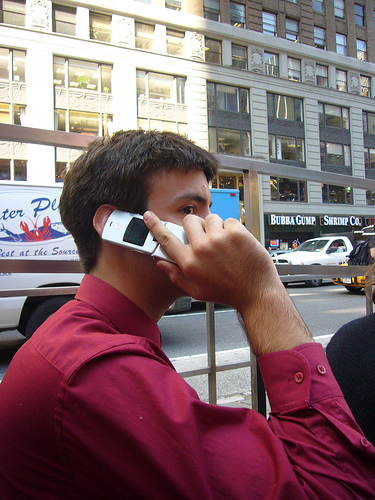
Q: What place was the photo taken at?
A: It was taken at the road.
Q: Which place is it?
A: It is a road.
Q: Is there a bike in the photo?
A: No, there are no bikes.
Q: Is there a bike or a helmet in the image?
A: No, there are no bikes or helmets.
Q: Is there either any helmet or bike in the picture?
A: No, there are no bikes or helmets.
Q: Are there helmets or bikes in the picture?
A: No, there are no bikes or helmets.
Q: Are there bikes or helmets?
A: No, there are no bikes or helmets.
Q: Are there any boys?
A: No, there are no boys.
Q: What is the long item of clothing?
A: The clothing item is a shirt.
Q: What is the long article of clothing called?
A: The clothing item is a shirt.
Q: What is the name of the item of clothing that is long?
A: The clothing item is a shirt.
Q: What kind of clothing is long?
A: The clothing is a shirt.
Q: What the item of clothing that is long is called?
A: The clothing item is a shirt.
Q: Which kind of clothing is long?
A: The clothing is a shirt.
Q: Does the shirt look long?
A: Yes, the shirt is long.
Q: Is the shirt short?
A: No, the shirt is long.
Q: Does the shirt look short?
A: No, the shirt is long.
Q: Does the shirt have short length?
A: No, the shirt is long.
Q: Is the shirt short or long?
A: The shirt is long.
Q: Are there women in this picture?
A: No, there are no women.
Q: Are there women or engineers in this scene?
A: No, there are no women or engineers.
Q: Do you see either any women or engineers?
A: No, there are no women or engineers.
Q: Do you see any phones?
A: Yes, there is a phone.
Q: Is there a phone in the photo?
A: Yes, there is a phone.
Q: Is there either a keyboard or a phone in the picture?
A: Yes, there is a phone.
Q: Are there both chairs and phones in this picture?
A: No, there is a phone but no chairs.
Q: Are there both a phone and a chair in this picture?
A: No, there is a phone but no chairs.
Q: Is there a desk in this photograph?
A: No, there are no desks.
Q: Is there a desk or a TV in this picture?
A: No, there are no desks or televisions.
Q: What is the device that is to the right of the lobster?
A: The device is a phone.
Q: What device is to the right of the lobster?
A: The device is a phone.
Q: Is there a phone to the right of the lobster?
A: Yes, there is a phone to the right of the lobster.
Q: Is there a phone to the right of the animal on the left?
A: Yes, there is a phone to the right of the lobster.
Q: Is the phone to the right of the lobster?
A: Yes, the phone is to the right of the lobster.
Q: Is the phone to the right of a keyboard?
A: No, the phone is to the right of the lobster.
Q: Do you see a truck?
A: Yes, there is a truck.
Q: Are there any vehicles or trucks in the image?
A: Yes, there is a truck.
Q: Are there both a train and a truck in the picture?
A: No, there is a truck but no trains.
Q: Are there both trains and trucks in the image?
A: No, there is a truck but no trains.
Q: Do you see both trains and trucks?
A: No, there is a truck but no trains.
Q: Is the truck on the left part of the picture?
A: No, the truck is on the right of the image.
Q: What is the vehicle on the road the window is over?
A: The vehicle is a truck.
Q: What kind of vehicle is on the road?
A: The vehicle is a truck.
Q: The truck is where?
A: The truck is on the road.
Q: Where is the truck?
A: The truck is on the road.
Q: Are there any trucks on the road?
A: Yes, there is a truck on the road.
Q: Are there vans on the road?
A: No, there is a truck on the road.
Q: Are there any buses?
A: No, there are no buses.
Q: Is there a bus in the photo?
A: No, there are no buses.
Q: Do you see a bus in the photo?
A: No, there are no buses.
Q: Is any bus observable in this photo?
A: No, there are no buses.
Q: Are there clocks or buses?
A: No, there are no buses or clocks.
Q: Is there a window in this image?
A: Yes, there is a window.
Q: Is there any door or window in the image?
A: Yes, there is a window.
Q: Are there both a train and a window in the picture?
A: No, there is a window but no trains.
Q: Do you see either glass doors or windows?
A: Yes, there is a glass window.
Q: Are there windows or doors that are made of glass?
A: Yes, the window is made of glass.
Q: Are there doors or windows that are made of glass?
A: Yes, the window is made of glass.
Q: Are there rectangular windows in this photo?
A: Yes, there is a rectangular window.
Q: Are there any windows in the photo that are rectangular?
A: Yes, there is a window that is rectangular.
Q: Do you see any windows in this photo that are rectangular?
A: Yes, there is a window that is rectangular.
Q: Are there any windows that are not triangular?
A: Yes, there is a rectangular window.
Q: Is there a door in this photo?
A: No, there are no doors.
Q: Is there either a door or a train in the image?
A: No, there are no doors or trains.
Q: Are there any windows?
A: Yes, there is a window.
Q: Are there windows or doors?
A: Yes, there is a window.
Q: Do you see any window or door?
A: Yes, there is a window.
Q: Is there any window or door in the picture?
A: Yes, there is a window.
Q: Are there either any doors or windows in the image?
A: Yes, there is a window.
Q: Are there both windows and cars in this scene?
A: Yes, there are both a window and a car.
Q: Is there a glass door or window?
A: Yes, there is a glass window.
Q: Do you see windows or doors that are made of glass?
A: Yes, the window is made of glass.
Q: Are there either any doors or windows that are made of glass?
A: Yes, the window is made of glass.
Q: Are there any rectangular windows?
A: Yes, there is a rectangular window.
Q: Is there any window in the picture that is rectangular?
A: Yes, there is a window that is rectangular.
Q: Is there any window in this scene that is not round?
A: Yes, there is a rectangular window.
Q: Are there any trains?
A: No, there are no trains.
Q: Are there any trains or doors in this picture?
A: No, there are no trains or doors.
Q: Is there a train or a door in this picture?
A: No, there are no trains or doors.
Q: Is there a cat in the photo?
A: No, there are no cats.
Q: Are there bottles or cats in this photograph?
A: No, there are no cats or bottles.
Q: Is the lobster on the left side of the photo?
A: Yes, the lobster is on the left of the image.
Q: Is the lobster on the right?
A: No, the lobster is on the left of the image.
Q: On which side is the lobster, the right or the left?
A: The lobster is on the left of the image.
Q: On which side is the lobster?
A: The lobster is on the left of the image.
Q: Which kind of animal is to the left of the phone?
A: The animal is a lobster.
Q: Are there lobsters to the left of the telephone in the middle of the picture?
A: Yes, there is a lobster to the left of the phone.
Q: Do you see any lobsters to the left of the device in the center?
A: Yes, there is a lobster to the left of the phone.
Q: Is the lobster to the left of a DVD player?
A: No, the lobster is to the left of the telephone.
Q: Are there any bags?
A: No, there are no bags.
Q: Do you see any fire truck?
A: No, there are no fire trucks.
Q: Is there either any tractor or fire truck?
A: No, there are no fire trucks or tractors.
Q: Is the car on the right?
A: Yes, the car is on the right of the image.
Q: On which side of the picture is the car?
A: The car is on the right of the image.